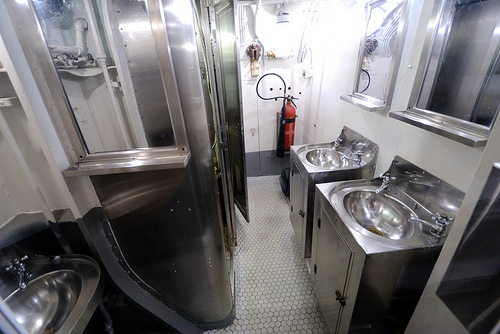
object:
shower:
[201, 7, 266, 231]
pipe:
[92, 7, 117, 141]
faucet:
[408, 211, 454, 241]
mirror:
[27, 0, 181, 158]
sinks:
[272, 121, 442, 263]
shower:
[31, 3, 239, 273]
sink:
[285, 130, 375, 178]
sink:
[335, 194, 420, 238]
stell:
[347, 91, 372, 109]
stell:
[82, 162, 96, 171]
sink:
[0, 250, 97, 334]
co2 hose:
[255, 72, 297, 108]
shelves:
[338, 97, 493, 137]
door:
[216, 0, 252, 230]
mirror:
[410, 3, 497, 138]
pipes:
[42, 40, 88, 57]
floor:
[244, 178, 319, 328]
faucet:
[3, 253, 32, 289]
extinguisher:
[255, 73, 297, 153]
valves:
[264, 42, 300, 68]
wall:
[234, 8, 317, 168]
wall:
[312, 1, 498, 194]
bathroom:
[0, 0, 499, 330]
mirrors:
[354, 2, 498, 148]